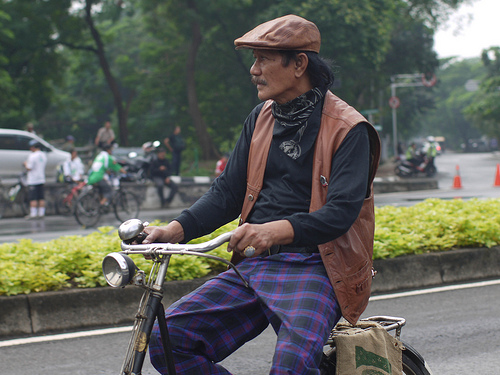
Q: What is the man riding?
A: A bicycle.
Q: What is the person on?
A: Bike.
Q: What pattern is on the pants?
A: Plaid.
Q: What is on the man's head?
A: Hat.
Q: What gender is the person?
A: Male.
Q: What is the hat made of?
A: Leather.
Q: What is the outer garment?
A: Vest.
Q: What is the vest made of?
A: Leather.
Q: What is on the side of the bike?
A: Bell.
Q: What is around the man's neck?
A: Bandana.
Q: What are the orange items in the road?
A: Cones.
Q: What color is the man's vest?
A: Brown.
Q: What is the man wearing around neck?
A: Scarf.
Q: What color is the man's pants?
A: Black and purple.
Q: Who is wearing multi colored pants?
A: Man on bike.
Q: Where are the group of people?
A: Background.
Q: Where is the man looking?
A: Away from camera.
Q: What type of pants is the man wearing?
A: Plaid.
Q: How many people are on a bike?
A: 2.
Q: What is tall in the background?
A: Trees.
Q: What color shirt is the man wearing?
A: Black.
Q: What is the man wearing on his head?
A: Hat.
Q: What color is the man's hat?
A: Brown.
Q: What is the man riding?
A: Bicycle.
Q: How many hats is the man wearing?
A: One.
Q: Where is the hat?
A: On the man's head.